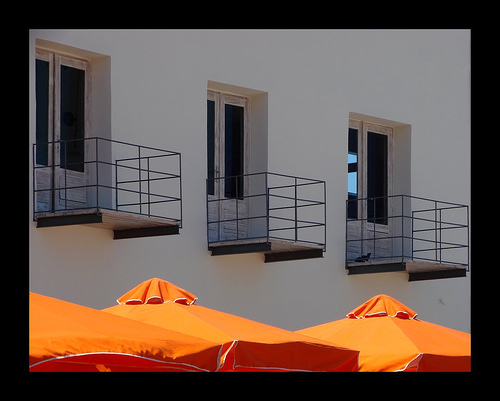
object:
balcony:
[203, 172, 325, 257]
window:
[349, 129, 357, 219]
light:
[347, 153, 357, 194]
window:
[225, 102, 243, 197]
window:
[207, 100, 214, 194]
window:
[366, 130, 387, 224]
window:
[33, 51, 51, 167]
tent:
[30, 290, 219, 372]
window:
[227, 104, 245, 203]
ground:
[380, 125, 398, 151]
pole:
[265, 171, 272, 243]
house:
[25, 30, 468, 372]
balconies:
[32, 137, 183, 236]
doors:
[35, 38, 91, 213]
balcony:
[203, 168, 324, 242]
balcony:
[343, 192, 468, 265]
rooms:
[343, 115, 409, 261]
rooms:
[32, 39, 110, 204]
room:
[207, 81, 247, 237]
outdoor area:
[26, 35, 468, 372]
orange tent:
[100, 276, 356, 370]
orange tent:
[289, 290, 468, 373]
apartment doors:
[201, 78, 271, 238]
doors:
[347, 119, 396, 263]